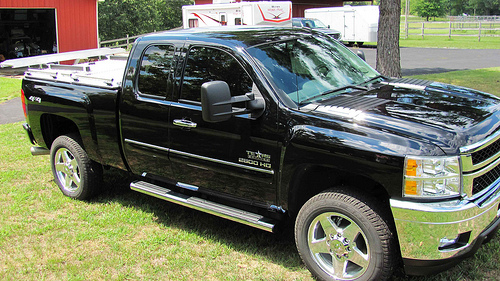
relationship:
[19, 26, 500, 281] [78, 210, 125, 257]
pickup truck on grass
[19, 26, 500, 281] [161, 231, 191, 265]
pickup truck on grass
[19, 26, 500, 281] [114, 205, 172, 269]
pickup truck on grass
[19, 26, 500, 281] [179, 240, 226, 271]
pickup truck on grass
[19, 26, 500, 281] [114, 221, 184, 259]
pickup truck on grass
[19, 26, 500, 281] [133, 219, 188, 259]
pickup truck on grass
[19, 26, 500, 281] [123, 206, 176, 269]
pickup truck on grass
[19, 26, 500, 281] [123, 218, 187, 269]
pickup truck on grass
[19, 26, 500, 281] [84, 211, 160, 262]
pickup truck on grass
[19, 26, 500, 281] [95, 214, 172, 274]
pickup truck on grass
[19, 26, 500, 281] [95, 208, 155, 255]
pickup truck on grass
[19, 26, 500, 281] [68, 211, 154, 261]
pickup truck on grass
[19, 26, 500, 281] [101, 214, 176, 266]
pickup truck on grass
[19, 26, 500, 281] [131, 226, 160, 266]
pickup truck on grass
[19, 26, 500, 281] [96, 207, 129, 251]
pickup truck on grass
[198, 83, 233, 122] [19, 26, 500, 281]
mirror of pickup truck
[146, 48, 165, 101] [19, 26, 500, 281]
window of pickup truck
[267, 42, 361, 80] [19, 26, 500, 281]
window of pickup truck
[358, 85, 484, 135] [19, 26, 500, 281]
hood of pickup truck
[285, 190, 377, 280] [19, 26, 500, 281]
wheel of pickup truck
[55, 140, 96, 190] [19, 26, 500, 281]
wheel of pickup truck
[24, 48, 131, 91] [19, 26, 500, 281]
bed of pickup truck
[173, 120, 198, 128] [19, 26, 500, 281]
door handle of pickup truck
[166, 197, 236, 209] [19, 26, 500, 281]
step of pickup truck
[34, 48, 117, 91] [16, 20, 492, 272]
bed of a pickup truck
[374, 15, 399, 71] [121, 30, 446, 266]
tree trunk on side of truck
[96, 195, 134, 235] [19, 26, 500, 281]
grass next to pickup truck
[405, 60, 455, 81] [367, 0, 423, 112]
shadow cast by tree